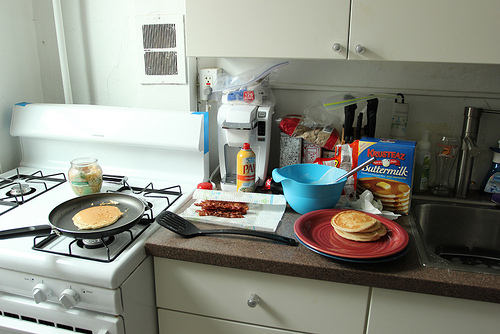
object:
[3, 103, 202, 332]
stove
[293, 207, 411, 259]
plate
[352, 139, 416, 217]
box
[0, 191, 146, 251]
skillet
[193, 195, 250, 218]
bacon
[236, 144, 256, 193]
cooking spray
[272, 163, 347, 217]
bowl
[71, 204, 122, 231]
pancakes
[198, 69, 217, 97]
electric outlet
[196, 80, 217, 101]
three prong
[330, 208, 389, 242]
pancakes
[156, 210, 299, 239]
spatula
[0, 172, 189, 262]
black burners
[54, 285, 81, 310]
knobs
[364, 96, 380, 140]
knifes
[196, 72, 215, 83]
one available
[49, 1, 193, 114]
wall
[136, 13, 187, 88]
exhaust vent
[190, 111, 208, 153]
masking tape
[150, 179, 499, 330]
counter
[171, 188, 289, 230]
paper towel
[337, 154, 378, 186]
whisk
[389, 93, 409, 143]
paper towel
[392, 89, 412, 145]
holder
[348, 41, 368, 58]
knobs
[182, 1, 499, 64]
cabinet doors